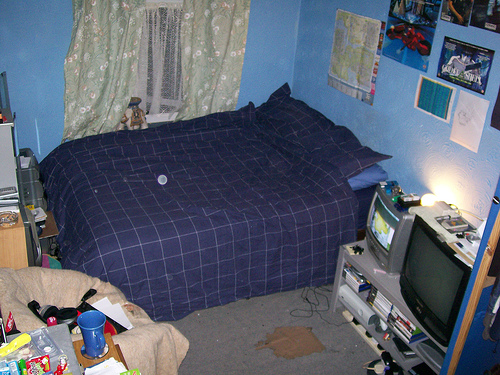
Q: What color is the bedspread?
A: Blue and white.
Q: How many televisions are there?
A: Two.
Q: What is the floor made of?
A: Carpet.